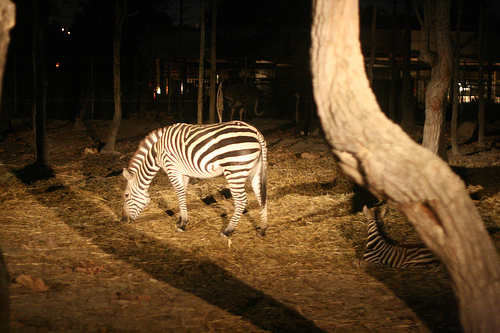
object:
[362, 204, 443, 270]
zebra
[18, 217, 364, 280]
hay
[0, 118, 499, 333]
ground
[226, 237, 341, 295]
dirt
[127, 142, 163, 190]
neck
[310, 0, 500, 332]
tree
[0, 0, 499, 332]
background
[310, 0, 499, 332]
tree trunk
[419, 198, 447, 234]
hole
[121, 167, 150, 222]
head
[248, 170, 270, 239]
legs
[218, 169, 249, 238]
back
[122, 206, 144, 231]
nose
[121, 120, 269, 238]
zebra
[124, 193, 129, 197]
eye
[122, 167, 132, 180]
ear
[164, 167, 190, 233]
leg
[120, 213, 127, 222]
nose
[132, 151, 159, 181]
mane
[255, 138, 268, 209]
tail